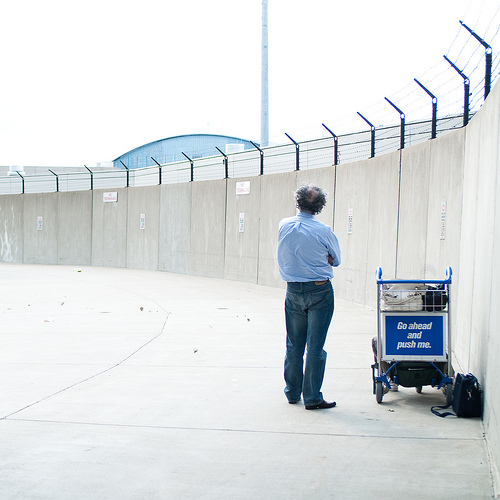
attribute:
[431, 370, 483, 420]
bag — black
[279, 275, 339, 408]
jeans — blue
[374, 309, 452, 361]
sign — white , blue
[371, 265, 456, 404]
cart — metal luggage, silver , blue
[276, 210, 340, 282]
shirt —  blue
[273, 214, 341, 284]
shirt — blue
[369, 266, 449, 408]
cart — luggage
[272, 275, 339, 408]
jeans — blue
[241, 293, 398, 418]
pants — dark dress 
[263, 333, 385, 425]
shoes — black dress, pair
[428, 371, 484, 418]
bag — black man's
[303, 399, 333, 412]
shoe —  large black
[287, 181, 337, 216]
hair — wild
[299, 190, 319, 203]
hair — long